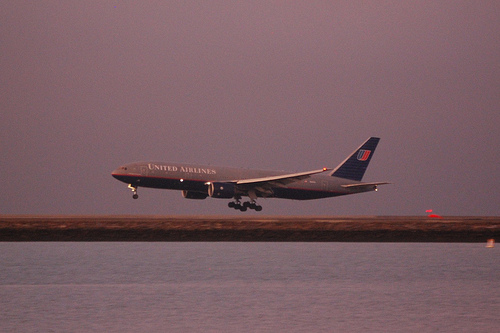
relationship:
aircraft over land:
[110, 136, 395, 212] [0, 213, 498, 240]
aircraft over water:
[110, 136, 395, 212] [3, 241, 496, 331]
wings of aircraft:
[321, 130, 411, 202] [87, 126, 402, 230]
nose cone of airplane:
[105, 165, 126, 183] [121, 122, 376, 228]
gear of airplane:
[223, 191, 265, 212] [98, 130, 402, 217]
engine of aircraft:
[204, 182, 240, 200] [104, 128, 398, 213]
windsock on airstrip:
[419, 201, 438, 222] [275, 217, 485, 225]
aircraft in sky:
[104, 128, 398, 213] [0, 1, 497, 218]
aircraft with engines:
[104, 128, 398, 213] [178, 183, 247, 203]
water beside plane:
[3, 241, 496, 331] [111, 133, 386, 209]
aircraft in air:
[110, 136, 395, 212] [9, 10, 484, 301]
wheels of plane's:
[125, 185, 142, 205] [109, 132, 389, 207]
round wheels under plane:
[227, 190, 259, 217] [119, 155, 376, 217]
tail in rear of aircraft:
[326, 119, 403, 196] [110, 136, 395, 212]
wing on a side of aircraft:
[203, 167, 330, 197] [110, 136, 395, 212]